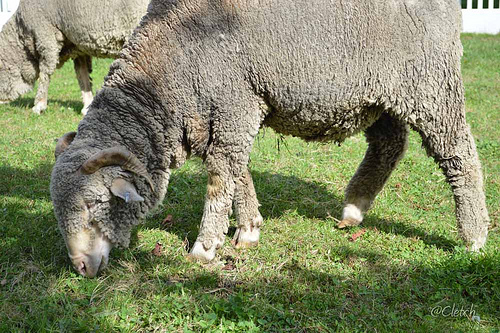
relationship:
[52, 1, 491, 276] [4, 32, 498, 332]
sheep eating grass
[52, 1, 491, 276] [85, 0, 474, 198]
sheep has wool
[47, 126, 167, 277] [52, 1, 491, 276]
head of sheep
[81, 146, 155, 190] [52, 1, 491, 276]
horn of sheep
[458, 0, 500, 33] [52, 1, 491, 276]
wall behind sheep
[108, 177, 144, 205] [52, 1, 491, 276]
ear of sheep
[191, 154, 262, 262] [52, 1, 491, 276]
front legs of sheep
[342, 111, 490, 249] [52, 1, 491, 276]
back legs of sheep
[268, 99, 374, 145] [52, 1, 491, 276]
belly of sheep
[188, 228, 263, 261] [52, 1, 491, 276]
hoof of sheep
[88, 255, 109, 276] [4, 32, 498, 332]
mouth on grass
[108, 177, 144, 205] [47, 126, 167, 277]
ear on head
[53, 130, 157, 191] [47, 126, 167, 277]
horns on head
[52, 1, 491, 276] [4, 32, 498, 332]
sheep grazing in grass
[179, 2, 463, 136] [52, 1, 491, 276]
body of sheep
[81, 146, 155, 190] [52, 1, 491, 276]
horn on sheep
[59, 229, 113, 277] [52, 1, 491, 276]
snout of sheep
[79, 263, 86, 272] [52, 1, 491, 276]
nostril of sheep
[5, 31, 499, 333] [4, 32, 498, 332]
field of grass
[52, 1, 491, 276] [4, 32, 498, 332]
sheep in grass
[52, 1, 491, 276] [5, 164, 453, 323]
sheep casting a shadow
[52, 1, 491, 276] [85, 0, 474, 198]
sheep raised for wool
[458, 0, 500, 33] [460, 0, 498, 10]
wall with windows